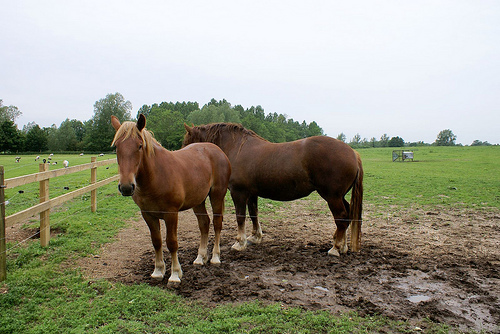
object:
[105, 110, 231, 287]
horse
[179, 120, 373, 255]
horse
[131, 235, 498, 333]
mud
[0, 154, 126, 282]
fence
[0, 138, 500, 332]
field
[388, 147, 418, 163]
irrigation equipment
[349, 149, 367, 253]
tail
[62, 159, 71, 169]
animal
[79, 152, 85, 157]
animal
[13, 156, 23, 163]
animal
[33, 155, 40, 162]
animal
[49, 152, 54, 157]
animal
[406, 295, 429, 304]
puddle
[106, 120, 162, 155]
mane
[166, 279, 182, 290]
hoof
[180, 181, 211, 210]
stomach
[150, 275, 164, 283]
hoof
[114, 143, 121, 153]
eye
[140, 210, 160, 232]
thigh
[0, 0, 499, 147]
sky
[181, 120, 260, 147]
hair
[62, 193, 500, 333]
corral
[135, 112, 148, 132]
ear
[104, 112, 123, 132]
ear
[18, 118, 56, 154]
tree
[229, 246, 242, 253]
hoof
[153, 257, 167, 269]
fetlock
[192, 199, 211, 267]
leg